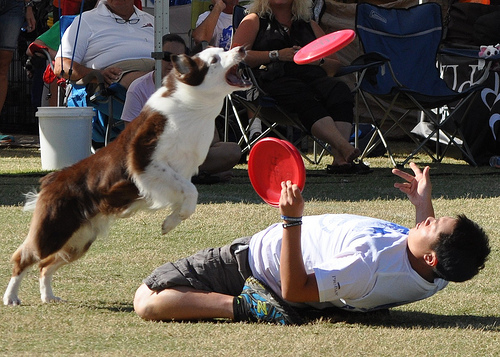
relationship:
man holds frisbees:
[124, 193, 493, 333] [238, 136, 315, 206]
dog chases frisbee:
[11, 33, 251, 285] [290, 21, 360, 71]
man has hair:
[131, 161, 493, 327] [449, 235, 481, 265]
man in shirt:
[124, 193, 493, 333] [256, 211, 411, 311]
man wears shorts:
[124, 193, 493, 333] [138, 228, 248, 304]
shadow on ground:
[393, 307, 492, 333] [296, 329, 465, 356]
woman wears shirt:
[240, 2, 378, 172] [248, 16, 333, 79]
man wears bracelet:
[124, 193, 493, 333] [276, 212, 306, 235]